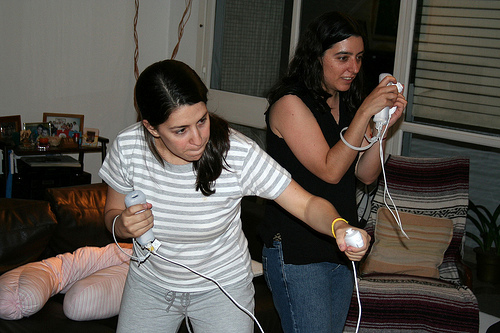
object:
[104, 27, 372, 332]
woman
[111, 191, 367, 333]
remote controls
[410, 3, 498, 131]
blind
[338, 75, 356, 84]
mouth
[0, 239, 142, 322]
pillow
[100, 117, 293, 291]
shirt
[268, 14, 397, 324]
girl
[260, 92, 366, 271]
shirt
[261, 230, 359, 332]
jeans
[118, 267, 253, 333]
sweatpants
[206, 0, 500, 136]
windows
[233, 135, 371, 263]
arm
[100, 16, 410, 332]
women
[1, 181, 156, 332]
sofa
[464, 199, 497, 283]
plant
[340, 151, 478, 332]
chair